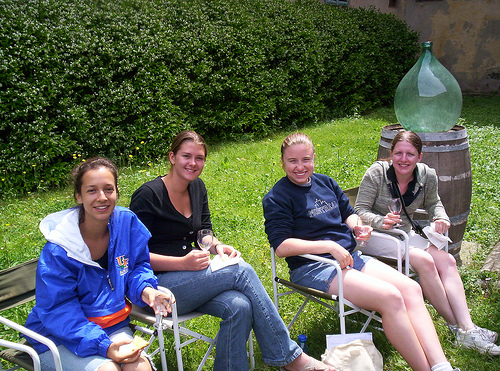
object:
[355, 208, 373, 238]
glasses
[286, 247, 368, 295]
shorts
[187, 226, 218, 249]
glass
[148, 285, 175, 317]
glass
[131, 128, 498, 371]
one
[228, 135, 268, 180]
flowers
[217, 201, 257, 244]
weeds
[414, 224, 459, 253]
napkin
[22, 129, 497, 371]
four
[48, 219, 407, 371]
relaxing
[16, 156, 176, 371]
person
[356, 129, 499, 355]
person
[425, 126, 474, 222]
barrel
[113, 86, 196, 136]
thick hedges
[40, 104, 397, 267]
yard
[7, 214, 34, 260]
grass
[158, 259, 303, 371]
jeans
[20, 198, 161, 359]
jacket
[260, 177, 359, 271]
sweater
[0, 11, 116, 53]
plant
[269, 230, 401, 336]
chair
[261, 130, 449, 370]
lady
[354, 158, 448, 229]
shirt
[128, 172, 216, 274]
shirt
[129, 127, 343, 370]
lady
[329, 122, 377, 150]
grass